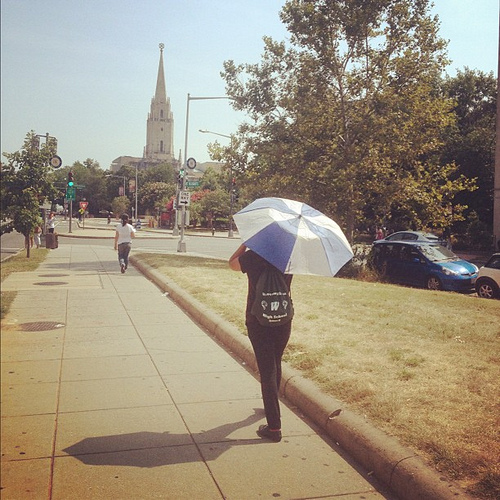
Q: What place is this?
A: It is a street.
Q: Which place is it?
A: It is a street.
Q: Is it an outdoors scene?
A: Yes, it is outdoors.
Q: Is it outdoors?
A: Yes, it is outdoors.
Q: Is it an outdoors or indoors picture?
A: It is outdoors.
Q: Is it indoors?
A: No, it is outdoors.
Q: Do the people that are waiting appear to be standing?
A: Yes, the people are standing.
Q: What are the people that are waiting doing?
A: The people are standing.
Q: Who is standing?
A: The people are standing.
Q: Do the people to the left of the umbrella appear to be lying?
A: No, the people are standing.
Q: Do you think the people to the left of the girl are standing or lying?
A: The people are standing.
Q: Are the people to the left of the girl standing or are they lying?
A: The people are standing.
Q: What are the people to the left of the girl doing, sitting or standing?
A: The people are standing.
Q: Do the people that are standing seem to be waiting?
A: Yes, the people are waiting.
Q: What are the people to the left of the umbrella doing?
A: The people are waiting.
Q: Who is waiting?
A: The people are waiting.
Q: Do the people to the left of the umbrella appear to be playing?
A: No, the people are waiting.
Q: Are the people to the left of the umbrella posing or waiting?
A: The people are waiting.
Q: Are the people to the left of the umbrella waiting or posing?
A: The people are waiting.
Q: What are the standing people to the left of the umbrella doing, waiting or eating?
A: The people are waiting.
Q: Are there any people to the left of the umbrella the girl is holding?
A: Yes, there are people to the left of the umbrella.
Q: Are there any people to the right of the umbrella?
A: No, the people are to the left of the umbrella.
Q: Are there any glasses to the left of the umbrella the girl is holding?
A: No, there are people to the left of the umbrella.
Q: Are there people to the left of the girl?
A: Yes, there are people to the left of the girl.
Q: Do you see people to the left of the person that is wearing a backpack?
A: Yes, there are people to the left of the girl.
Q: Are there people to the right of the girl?
A: No, the people are to the left of the girl.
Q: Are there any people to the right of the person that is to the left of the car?
A: No, the people are to the left of the girl.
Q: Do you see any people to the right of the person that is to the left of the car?
A: No, the people are to the left of the girl.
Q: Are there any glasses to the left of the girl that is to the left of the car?
A: No, there are people to the left of the girl.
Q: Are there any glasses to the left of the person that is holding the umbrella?
A: No, there are people to the left of the girl.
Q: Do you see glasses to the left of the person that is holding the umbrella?
A: No, there are people to the left of the girl.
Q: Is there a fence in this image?
A: No, there are no fences.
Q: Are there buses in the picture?
A: No, there are no buses.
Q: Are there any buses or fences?
A: No, there are no buses or fences.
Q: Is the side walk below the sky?
A: Yes, the side walk is below the sky.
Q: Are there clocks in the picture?
A: No, there are no clocks.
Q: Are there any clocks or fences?
A: No, there are no clocks or fences.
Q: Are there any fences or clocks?
A: No, there are no clocks or fences.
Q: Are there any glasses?
A: No, there are no glasses.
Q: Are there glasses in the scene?
A: No, there are no glasses.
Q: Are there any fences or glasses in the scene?
A: No, there are no glasses or fences.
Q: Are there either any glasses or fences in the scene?
A: No, there are no glasses or fences.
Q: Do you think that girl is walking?
A: Yes, the girl is walking.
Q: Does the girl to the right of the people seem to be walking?
A: Yes, the girl is walking.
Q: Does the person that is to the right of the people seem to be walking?
A: Yes, the girl is walking.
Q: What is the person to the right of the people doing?
A: The girl is walking.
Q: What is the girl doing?
A: The girl is walking.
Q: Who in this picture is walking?
A: The girl is walking.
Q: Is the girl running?
A: No, the girl is walking.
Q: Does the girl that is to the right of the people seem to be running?
A: No, the girl is walking.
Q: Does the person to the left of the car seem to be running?
A: No, the girl is walking.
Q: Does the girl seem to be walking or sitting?
A: The girl is walking.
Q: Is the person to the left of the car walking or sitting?
A: The girl is walking.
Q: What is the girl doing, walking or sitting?
A: The girl is walking.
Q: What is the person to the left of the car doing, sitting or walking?
A: The girl is walking.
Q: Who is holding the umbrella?
A: The girl is holding the umbrella.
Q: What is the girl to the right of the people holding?
A: The girl is holding the umbrella.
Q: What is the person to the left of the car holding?
A: The girl is holding the umbrella.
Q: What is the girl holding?
A: The girl is holding the umbrella.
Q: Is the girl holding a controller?
A: No, the girl is holding the umbrella.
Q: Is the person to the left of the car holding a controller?
A: No, the girl is holding the umbrella.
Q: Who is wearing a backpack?
A: The girl is wearing a backpack.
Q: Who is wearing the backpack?
A: The girl is wearing a backpack.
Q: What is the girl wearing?
A: The girl is wearing a backpack.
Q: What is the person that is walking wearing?
A: The girl is wearing a backpack.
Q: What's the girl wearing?
A: The girl is wearing a backpack.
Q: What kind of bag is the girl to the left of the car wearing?
A: The girl is wearing a backpack.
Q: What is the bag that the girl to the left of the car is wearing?
A: The bag is a backpack.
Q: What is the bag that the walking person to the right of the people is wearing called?
A: The bag is a backpack.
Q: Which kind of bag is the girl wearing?
A: The girl is wearing a backpack.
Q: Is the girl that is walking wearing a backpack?
A: Yes, the girl is wearing a backpack.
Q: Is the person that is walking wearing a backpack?
A: Yes, the girl is wearing a backpack.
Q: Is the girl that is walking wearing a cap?
A: No, the girl is wearing a backpack.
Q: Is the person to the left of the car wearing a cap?
A: No, the girl is wearing a backpack.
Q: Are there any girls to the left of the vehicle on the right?
A: Yes, there is a girl to the left of the car.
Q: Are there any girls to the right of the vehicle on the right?
A: No, the girl is to the left of the car.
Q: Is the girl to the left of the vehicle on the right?
A: Yes, the girl is to the left of the car.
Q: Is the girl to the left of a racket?
A: No, the girl is to the left of the car.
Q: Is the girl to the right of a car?
A: No, the girl is to the left of a car.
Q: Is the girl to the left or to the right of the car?
A: The girl is to the left of the car.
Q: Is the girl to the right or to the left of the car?
A: The girl is to the left of the car.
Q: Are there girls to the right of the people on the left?
A: Yes, there is a girl to the right of the people.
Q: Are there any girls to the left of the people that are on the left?
A: No, the girl is to the right of the people.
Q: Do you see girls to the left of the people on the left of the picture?
A: No, the girl is to the right of the people.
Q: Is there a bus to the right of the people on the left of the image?
A: No, there is a girl to the right of the people.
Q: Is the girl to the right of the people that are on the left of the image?
A: Yes, the girl is to the right of the people.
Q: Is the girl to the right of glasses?
A: No, the girl is to the right of the people.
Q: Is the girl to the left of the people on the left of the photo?
A: No, the girl is to the right of the people.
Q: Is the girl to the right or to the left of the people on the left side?
A: The girl is to the right of the people.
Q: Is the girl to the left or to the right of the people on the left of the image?
A: The girl is to the right of the people.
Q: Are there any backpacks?
A: Yes, there is a backpack.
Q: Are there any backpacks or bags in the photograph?
A: Yes, there is a backpack.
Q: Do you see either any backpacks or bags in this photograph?
A: Yes, there is a backpack.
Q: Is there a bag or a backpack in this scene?
A: Yes, there is a backpack.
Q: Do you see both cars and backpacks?
A: Yes, there are both a backpack and a car.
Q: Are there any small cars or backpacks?
A: Yes, there is a small backpack.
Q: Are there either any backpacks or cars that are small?
A: Yes, the backpack is small.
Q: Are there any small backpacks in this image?
A: Yes, there is a small backpack.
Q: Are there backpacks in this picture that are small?
A: Yes, there is a backpack that is small.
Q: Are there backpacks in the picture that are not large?
A: Yes, there is a small backpack.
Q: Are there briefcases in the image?
A: No, there are no briefcases.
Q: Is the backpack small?
A: Yes, the backpack is small.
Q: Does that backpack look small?
A: Yes, the backpack is small.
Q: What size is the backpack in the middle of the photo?
A: The backpack is small.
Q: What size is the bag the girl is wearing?
A: The backpack is small.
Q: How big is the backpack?
A: The backpack is small.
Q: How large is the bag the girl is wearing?
A: The backpack is small.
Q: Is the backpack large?
A: No, the backpack is small.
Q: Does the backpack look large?
A: No, the backpack is small.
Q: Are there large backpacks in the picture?
A: No, there is a backpack but it is small.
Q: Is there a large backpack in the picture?
A: No, there is a backpack but it is small.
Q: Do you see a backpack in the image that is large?
A: No, there is a backpack but it is small.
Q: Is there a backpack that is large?
A: No, there is a backpack but it is small.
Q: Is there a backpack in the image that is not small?
A: No, there is a backpack but it is small.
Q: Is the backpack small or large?
A: The backpack is small.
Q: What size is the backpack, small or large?
A: The backpack is small.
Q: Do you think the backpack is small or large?
A: The backpack is small.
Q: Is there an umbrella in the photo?
A: Yes, there is an umbrella.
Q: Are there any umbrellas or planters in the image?
A: Yes, there is an umbrella.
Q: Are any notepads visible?
A: No, there are no notepads.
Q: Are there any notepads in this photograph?
A: No, there are no notepads.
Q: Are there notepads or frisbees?
A: No, there are no notepads or frisbees.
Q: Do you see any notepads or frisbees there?
A: No, there are no notepads or frisbees.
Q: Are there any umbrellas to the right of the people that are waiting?
A: Yes, there is an umbrella to the right of the people.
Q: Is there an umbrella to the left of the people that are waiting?
A: No, the umbrella is to the right of the people.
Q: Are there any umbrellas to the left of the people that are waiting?
A: No, the umbrella is to the right of the people.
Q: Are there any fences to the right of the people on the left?
A: No, there is an umbrella to the right of the people.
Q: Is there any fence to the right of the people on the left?
A: No, there is an umbrella to the right of the people.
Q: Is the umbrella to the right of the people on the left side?
A: Yes, the umbrella is to the right of the people.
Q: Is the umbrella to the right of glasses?
A: No, the umbrella is to the right of the people.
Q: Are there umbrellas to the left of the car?
A: Yes, there is an umbrella to the left of the car.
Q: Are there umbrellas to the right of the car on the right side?
A: No, the umbrella is to the left of the car.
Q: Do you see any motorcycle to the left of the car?
A: No, there is an umbrella to the left of the car.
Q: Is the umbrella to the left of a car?
A: Yes, the umbrella is to the left of a car.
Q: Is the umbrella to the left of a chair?
A: No, the umbrella is to the left of a car.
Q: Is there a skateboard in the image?
A: No, there are no skateboards.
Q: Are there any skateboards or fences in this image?
A: No, there are no skateboards or fences.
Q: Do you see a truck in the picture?
A: No, there are no trucks.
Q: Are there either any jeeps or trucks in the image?
A: No, there are no trucks or jeeps.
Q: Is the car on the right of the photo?
A: Yes, the car is on the right of the image.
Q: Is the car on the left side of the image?
A: No, the car is on the right of the image.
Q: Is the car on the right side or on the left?
A: The car is on the right of the image.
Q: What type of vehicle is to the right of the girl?
A: The vehicle is a car.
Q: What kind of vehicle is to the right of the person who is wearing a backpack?
A: The vehicle is a car.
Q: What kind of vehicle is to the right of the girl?
A: The vehicle is a car.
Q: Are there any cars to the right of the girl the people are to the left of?
A: Yes, there is a car to the right of the girl.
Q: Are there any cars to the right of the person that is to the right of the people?
A: Yes, there is a car to the right of the girl.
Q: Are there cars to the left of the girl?
A: No, the car is to the right of the girl.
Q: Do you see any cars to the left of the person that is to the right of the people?
A: No, the car is to the right of the girl.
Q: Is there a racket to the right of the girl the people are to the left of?
A: No, there is a car to the right of the girl.